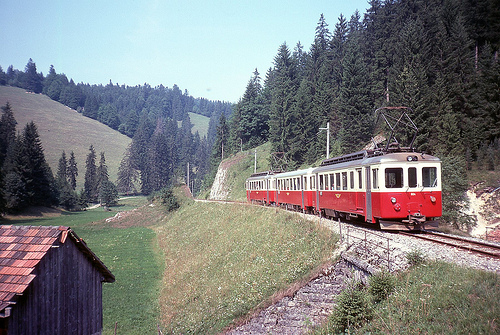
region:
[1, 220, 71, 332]
brown shingles on roof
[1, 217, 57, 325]
roof with brown shingles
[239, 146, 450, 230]
a train on tracks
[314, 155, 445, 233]
first car on train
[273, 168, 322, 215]
second car on train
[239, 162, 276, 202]
last car on train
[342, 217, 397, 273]
metal fence by train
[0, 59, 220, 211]
tall trees behind train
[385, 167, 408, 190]
window of a train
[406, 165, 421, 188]
window of a train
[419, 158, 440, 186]
window of a train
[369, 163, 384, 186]
window of a train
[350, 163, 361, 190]
window of a train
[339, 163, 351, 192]
window of a train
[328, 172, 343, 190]
window of a train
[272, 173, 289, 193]
window of a train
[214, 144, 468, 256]
this is a train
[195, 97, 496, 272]
train is on the tracks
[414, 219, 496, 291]
a set of train tracks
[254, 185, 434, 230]
red bottom of train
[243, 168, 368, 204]
row of windows on train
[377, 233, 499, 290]
gravel next to train tracks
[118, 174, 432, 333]
this is a hillside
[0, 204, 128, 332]
this is a building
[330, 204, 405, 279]
railing on side of the tracks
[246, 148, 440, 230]
red and white train in the mountains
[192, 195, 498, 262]
a train track though the mountains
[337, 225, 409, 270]
a bridge near the front of the train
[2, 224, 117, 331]
an old wooden barn by the train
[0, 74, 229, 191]
mountains in the background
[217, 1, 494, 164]
tall hillside covered in trees next to train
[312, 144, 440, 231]
the train's front car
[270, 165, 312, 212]
the train's middle car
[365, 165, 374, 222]
door on first car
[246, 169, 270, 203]
last car on the train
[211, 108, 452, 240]
red and white train on a track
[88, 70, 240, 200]
pine trees on a mountain side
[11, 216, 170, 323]
old wooden shack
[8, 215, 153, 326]
small wooden shack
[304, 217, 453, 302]
rocks near a train track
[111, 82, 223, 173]
many large pine trees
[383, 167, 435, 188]
windows on a train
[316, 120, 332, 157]
tall post near a train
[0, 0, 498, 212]
pine trees on grassy hills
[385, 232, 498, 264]
gravel along train tracks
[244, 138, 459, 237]
train on the track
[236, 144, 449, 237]
red and white colored train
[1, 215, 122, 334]
old small building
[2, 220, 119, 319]
old shingled roof on a shed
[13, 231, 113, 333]
wooden walls of a small building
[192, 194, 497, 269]
long metal train tracks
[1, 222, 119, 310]
red square shaped shingles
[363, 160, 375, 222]
door on the side of the train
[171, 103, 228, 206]
smoke by green trees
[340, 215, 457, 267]
metal rail by train tracks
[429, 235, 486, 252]
grey rocks by rusty train tracks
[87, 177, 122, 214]
small green tree by gravel road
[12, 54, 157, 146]
green trees on far side of hill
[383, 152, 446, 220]
lights on front of train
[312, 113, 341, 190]
grey metal pole behind train